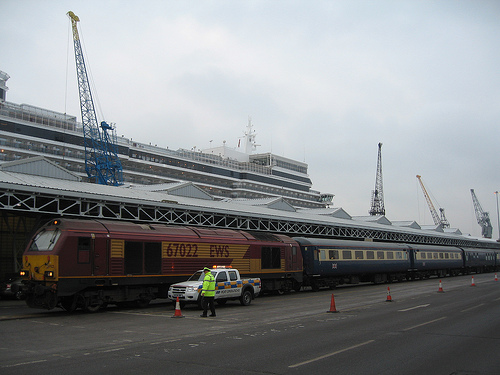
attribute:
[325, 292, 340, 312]
cone — orange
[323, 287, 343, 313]
cone — orange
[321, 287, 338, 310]
cone — orange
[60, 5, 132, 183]
crane — blue, yellow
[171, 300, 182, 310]
stripe — white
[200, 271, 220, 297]
jacket — yellow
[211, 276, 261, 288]
checkers — blue, yellow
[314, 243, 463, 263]
stripe — yellow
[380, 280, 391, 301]
cone — orange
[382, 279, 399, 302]
cone — orange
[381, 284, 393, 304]
cone — orange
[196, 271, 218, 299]
vest — green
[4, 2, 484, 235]
sky — white